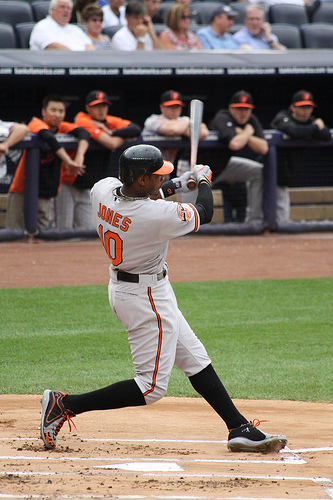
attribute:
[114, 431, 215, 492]
plate — home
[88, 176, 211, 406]
baseball uniform — grey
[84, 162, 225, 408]
uniform — grey, orange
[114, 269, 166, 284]
belt — black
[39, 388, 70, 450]
shoe — white, black, orange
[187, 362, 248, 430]
socks — black, long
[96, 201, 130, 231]
jones — name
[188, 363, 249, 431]
sock — black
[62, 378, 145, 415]
sock — black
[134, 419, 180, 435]
dirt — brown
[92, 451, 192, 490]
plate — home, white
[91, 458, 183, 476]
home plate — white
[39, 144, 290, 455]
man — black, orange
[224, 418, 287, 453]
shoe — grey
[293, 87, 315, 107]
hat — for baseball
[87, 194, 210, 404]
uniform — white, black, orange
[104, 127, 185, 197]
helmet — black, for baseball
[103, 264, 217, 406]
pants — grey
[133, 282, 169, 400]
stripe — orange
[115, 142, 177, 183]
hat — black, hard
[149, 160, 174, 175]
visor — orange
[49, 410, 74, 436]
shoe laces — orange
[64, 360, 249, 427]
socks — black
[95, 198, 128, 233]
letters — orange